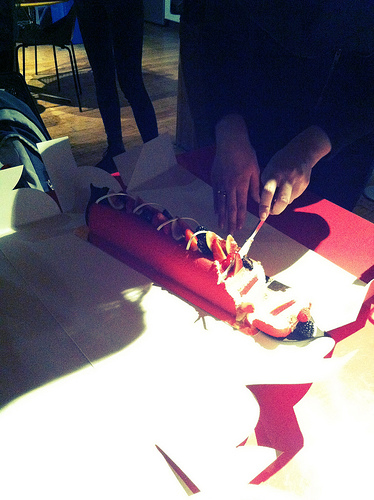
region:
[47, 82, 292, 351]
this is a suchi cake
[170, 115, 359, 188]
she is cutting the cake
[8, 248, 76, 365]
this is a white box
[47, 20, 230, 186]
this is are legs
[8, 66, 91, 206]
this is white cake box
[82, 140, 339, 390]
this is an indoor shot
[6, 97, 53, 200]
this is a bag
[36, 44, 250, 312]
this is an indoor photo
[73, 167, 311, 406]
this is a nice photo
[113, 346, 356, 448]
i like this image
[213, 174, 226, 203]
A ring is on the person's right hand.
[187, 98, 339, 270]
The person is using a knife.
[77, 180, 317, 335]
A cake shaped like a cylinder.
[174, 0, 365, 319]
The person is cutting a piece of the cake.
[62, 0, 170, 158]
A person standing in the background.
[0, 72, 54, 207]
A backpack.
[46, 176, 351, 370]
The cake is on top of the box it came in.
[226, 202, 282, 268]
A stainless steel knife.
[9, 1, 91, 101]
A chair in the background.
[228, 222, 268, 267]
Knife cutting the cake into slices.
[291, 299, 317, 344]
A raspberry and a blackberry.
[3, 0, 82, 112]
Table and chairs in background.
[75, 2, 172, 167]
A person's two legs.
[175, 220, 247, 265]
Fruit on top of cake.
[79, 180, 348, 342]
Cake that is being sliced.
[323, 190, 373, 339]
Part of box that cake is in.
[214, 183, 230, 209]
The ring on this person's hand.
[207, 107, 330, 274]
Person using knife to slice cake.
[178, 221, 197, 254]
Sliced strawberry on cake.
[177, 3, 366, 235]
woman cutting cake with knife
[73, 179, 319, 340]
long cylindrical cake with fruit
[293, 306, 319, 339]
raspberry and blackberry on cake slice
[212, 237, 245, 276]
strawberry slices on top of cake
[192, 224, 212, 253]
whole blackberries on top of cake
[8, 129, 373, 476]
white cardboard cake box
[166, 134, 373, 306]
red table top under box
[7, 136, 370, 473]
box unfolded around cake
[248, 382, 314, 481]
shadow cast by cake box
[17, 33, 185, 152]
brown wooden floor planks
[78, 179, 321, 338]
long and slender cake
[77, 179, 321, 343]
elaborate cake with fruit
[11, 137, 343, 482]
white bakery cake box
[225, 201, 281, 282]
silver knife cutting cake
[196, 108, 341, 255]
woman cutting the cake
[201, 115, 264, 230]
woman wearing a ring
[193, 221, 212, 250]
whole blackberries on cake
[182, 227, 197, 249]
strawberry slice on cake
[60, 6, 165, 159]
black leggings in the background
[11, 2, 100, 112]
dark chair in the next room